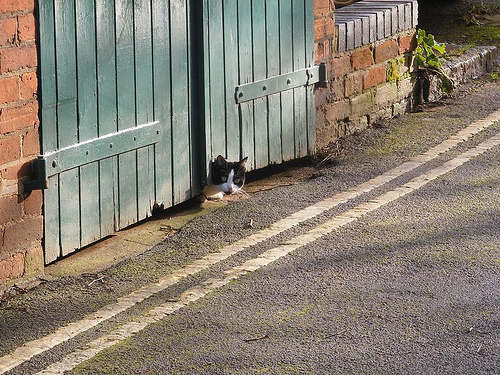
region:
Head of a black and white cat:
[204, 147, 250, 206]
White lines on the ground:
[92, 98, 493, 374]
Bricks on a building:
[338, 55, 410, 117]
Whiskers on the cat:
[212, 179, 256, 204]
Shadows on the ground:
[440, 179, 496, 272]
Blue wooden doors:
[23, 0, 321, 264]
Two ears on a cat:
[212, 152, 252, 174]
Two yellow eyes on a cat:
[214, 169, 246, 188]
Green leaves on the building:
[406, 23, 455, 93]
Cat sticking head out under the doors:
[169, 109, 265, 209]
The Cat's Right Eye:
[217, 173, 229, 185]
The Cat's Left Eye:
[232, 173, 240, 185]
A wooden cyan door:
[50, 0, 195, 255]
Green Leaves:
[408, 28, 443, 72]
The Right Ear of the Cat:
[215, 154, 227, 166]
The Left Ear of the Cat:
[232, 154, 250, 170]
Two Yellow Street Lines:
[254, 170, 452, 266]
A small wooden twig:
[242, 330, 276, 345]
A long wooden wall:
[0, 1, 40, 283]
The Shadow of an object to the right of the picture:
[280, 202, 499, 292]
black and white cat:
[198, 153, 275, 210]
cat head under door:
[146, 109, 283, 251]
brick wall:
[328, 10, 422, 134]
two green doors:
[34, 3, 301, 153]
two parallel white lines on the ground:
[172, 243, 278, 304]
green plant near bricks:
[400, 22, 466, 95]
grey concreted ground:
[300, 260, 490, 365]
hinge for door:
[30, 135, 72, 190]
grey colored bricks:
[335, 3, 430, 49]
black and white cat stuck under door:
[183, 130, 276, 229]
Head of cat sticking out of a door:
[196, 151, 257, 211]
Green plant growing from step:
[404, 26, 446, 75]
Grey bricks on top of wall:
[336, 1, 418, 49]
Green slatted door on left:
[33, 4, 195, 256]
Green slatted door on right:
[196, 3, 326, 168]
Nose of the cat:
[223, 184, 236, 194]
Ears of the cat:
[208, 150, 257, 168]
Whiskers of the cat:
[231, 189, 253, 201]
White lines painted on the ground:
[6, 100, 496, 371]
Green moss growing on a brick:
[383, 56, 414, 78]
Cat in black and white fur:
[201, 149, 252, 206]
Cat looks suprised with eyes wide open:
[217, 170, 242, 195]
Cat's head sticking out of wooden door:
[166, 135, 270, 216]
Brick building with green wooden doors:
[0, 0, 416, 151]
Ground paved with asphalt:
[262, 177, 499, 374]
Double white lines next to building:
[56, 265, 231, 370]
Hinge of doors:
[17, 116, 77, 206]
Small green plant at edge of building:
[405, 24, 447, 79]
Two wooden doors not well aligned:
[14, 60, 329, 190]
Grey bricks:
[327, 3, 413, 65]